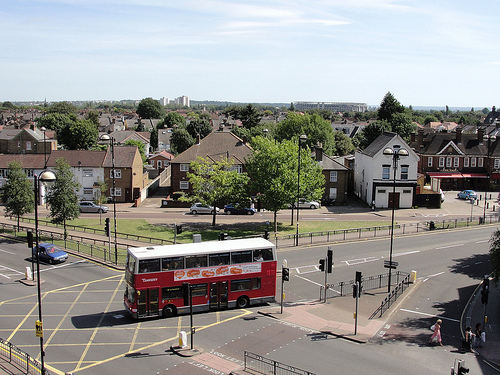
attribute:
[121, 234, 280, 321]
bus — doubledecker, red, white, moving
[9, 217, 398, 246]
grass — green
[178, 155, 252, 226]
tree — green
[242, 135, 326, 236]
tree — green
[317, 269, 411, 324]
fence — metal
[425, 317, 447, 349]
woman — walking, crossing street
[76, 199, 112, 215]
car — silver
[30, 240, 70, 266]
car — blue, waiting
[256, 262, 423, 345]
concrete area — triangular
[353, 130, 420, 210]
house — white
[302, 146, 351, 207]
house — brown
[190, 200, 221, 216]
car — white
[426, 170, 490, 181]
awning — red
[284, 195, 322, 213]
car — white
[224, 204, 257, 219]
car — blue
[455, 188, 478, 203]
car — blue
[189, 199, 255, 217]
cars — parked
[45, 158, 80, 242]
tree — green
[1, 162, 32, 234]
tree — green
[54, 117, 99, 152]
tree — green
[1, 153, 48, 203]
house — white